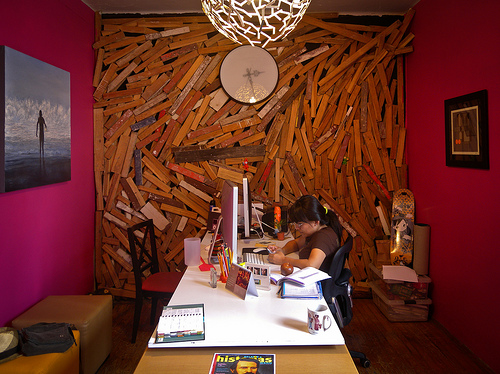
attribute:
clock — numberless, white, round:
[219, 45, 277, 104]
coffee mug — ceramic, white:
[308, 304, 331, 334]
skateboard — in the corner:
[389, 188, 414, 267]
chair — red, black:
[126, 218, 182, 340]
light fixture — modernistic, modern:
[201, 0, 310, 46]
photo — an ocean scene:
[2, 44, 74, 191]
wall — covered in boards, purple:
[2, 1, 98, 329]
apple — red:
[281, 261, 295, 277]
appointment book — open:
[155, 304, 205, 345]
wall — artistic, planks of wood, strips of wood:
[91, 14, 417, 298]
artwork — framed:
[445, 88, 488, 168]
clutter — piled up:
[365, 188, 436, 323]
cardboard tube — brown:
[413, 221, 429, 277]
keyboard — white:
[241, 250, 266, 273]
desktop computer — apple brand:
[222, 180, 282, 271]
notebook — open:
[273, 266, 330, 287]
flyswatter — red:
[199, 253, 213, 270]